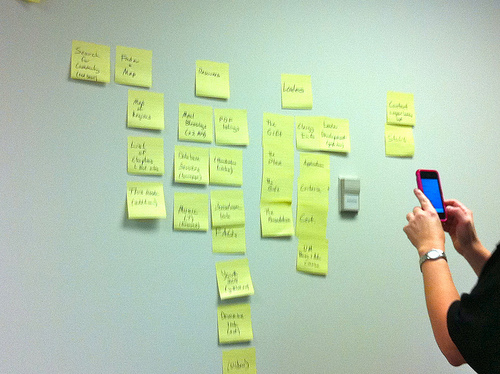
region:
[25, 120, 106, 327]
this is a wall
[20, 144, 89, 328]
the wall is white in color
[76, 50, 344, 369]
these are several stickers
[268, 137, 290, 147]
the sticker is yellow in color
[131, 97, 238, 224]
there are writings on the stickers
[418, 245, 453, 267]
this is a wrist watch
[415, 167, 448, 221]
this is a mobile phone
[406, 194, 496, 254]
the man is holding the phone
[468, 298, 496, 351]
this is a t-shirt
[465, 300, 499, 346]
the t-shirt is black in color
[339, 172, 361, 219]
white thermostat on wall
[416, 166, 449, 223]
cell phone with pink case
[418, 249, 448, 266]
silver metal watch on wrist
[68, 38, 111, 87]
yellow post it note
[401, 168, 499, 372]
person taking cell phone picture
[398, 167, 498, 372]
person wearing black shirt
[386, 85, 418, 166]
sticker notes on wall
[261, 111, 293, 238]
reminders stuck on wall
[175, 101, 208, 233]
directions sticking to wall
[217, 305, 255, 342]
yellow note stuck on wall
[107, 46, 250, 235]
post it notes on wall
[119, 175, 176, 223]
yellow paper with writing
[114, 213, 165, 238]
shadow of paper on wall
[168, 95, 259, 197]
square yellow papers on white wall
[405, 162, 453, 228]
cell phone in two hands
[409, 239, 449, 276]
watch on woman's wrist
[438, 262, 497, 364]
short black sleeve on arm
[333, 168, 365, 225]
rectangle box on wall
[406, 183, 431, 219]
extended index finger on woman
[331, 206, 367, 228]
shadow of box on wall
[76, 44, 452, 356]
WHITE WALL WITH YELLOW POST ITS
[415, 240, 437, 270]
SILVER WATCH ON LEFT ARM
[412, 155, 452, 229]
RED AND BLACK SMARTPHONE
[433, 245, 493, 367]
BLACK T SHIRT SLEEVE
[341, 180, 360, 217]
TAN THERMOSTAT ON WHITE WALL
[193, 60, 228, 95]
YELLOW POST IT NOTE ON WHITE WALL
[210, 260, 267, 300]
YELLOW POST IT NOTE ON WHITE WALL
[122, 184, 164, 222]
YELLOW POST IT NOTE ON WHITE WALL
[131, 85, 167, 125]
YELLOW POST IT NOTE ON WHITE WALL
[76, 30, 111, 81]
YELLOW POST IT NOTE ON WHITE WALL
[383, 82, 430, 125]
a yellow post it note.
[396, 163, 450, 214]
a smart device in a person's hand.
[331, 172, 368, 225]
a thermostat.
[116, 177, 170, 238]
a yellow post it note.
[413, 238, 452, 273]
a watch on a wrist.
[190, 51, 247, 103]
writing on a post it.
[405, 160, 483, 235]
hands holding a phone.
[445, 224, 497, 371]
a person wearing a black shirt.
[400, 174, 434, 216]
a pointer finger.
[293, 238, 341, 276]
black writing on paper.